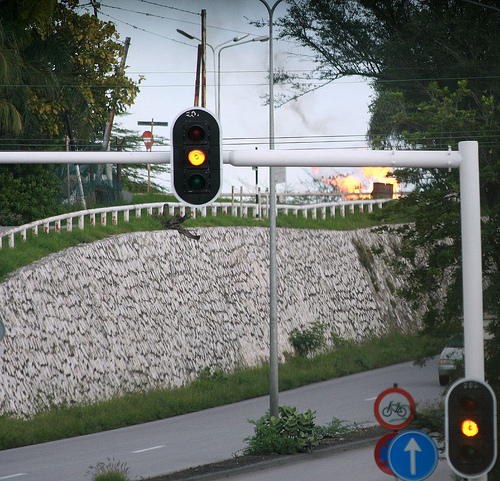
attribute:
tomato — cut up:
[175, 226, 216, 258]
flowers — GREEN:
[40, 94, 62, 134]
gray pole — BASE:
[261, 0, 281, 416]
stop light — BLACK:
[443, 377, 498, 479]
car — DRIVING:
[437, 345, 488, 390]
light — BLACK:
[139, 96, 249, 233]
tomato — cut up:
[191, 463, 199, 473]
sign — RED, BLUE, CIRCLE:
[373, 432, 398, 477]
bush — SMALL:
[242, 398, 323, 458]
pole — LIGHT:
[53, 126, 484, 253]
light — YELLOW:
[157, 93, 262, 228]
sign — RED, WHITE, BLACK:
[371, 384, 416, 427]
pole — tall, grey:
[259, 0, 281, 419]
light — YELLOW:
[171, 109, 223, 208]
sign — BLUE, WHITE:
[382, 428, 441, 478]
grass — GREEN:
[54, 405, 108, 432]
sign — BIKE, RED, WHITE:
[373, 385, 419, 432]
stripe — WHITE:
[131, 439, 173, 461]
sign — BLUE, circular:
[365, 415, 459, 479]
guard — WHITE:
[46, 177, 300, 285]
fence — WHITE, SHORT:
[5, 216, 83, 235]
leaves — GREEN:
[246, 404, 327, 450]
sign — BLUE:
[385, 427, 440, 479]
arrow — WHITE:
[401, 434, 423, 479]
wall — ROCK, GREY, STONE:
[5, 215, 498, 413]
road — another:
[0, 221, 82, 232]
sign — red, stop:
[142, 131, 154, 147]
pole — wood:
[141, 148, 151, 195]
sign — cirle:
[365, 375, 423, 436]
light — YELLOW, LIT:
[163, 101, 259, 214]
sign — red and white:
[368, 397, 410, 419]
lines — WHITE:
[117, 440, 184, 458]